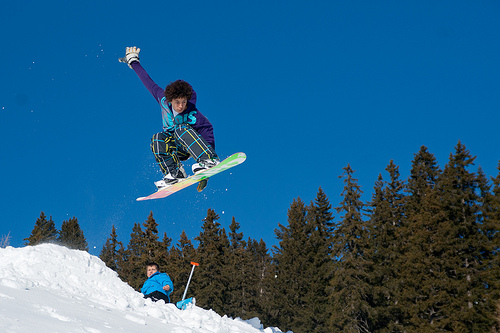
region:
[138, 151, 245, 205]
Boy on a snowboard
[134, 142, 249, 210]
Boy is on a snowboard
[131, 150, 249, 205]
Boy on a board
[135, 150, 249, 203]
Boy is on a board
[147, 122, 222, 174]
Boy wearing pants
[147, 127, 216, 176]
Boy is wearing pants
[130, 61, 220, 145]
Boy wearing a sweatshirt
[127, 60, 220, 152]
Boy is wearing a sweatshirt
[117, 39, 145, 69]
Boy is wearing gloves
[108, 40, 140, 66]
Boy is wearing white gloves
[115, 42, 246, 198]
snowboarder flying through the air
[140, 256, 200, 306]
man in blue jacket next to the shovel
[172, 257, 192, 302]
blue shovel with orange silver and orange handle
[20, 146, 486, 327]
forest of evergreen trees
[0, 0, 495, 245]
clear blue sky above the trees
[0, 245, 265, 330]
snow-covered ski slope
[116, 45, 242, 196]
snowboarder doing a trick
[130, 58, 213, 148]
snowboarder's purple sweatshirt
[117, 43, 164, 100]
boarder's right arm extended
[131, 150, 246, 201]
a green, pink and white snowboard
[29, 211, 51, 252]
tree is next to tree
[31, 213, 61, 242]
tree is next to tree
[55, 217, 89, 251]
tree is next to tree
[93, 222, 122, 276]
tree is next to tree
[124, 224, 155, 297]
tree is next to tree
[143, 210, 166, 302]
tree is next to tree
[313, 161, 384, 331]
tree is next to tree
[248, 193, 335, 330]
tree is next to tree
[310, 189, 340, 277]
tree is next to tree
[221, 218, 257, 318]
tree is next to tree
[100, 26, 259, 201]
the man is snowboarding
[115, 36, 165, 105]
man's arm in the air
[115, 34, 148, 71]
man wearing white glove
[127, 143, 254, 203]
the snowboard is white red and green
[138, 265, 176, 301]
man's jacket is blue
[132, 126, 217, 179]
blue and yellow lines on man's pants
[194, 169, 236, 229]
snow falling down from snowboard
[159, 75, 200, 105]
man's hair is brown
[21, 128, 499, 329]
pine trees behind the men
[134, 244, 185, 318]
man is watching man in air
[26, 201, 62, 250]
The tree is green.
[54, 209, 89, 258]
The tree is green.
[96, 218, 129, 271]
The tree is green.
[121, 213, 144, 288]
The tree is green.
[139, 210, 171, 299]
The tree is green.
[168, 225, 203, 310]
The tree is green.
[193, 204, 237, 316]
The tree is green.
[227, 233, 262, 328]
The tree is green.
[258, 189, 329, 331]
The tree is green.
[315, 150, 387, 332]
The tree is green.